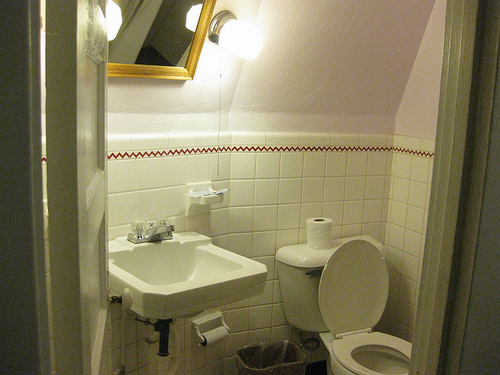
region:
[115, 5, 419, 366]
this room is a small bathroom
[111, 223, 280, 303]
this is the sink for the bathroom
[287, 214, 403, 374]
this is the toilet for the bathroom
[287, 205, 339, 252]
a roll of toilet paper sits on the tank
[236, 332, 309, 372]
there is a garbage can next to the toilet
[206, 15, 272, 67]
this is the light for the bathroom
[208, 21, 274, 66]
the light in the bathroom is on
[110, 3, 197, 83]
this is a mirror hanging on the wall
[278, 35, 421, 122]
the portion of the wall is painted white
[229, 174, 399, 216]
this portion of the wall is made up of white tile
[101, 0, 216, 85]
The mirror on the wall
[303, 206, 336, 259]
The toilet paper on the toilet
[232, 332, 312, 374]
The small trash can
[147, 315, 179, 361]
The black pipe under the sink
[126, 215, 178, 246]
The silver faucet of the sink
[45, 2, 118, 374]
The door of the bathroom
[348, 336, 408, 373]
The opening of the toilet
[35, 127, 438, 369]
The tile on the wall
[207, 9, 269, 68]
The light to the right of the mirror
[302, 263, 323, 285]
The handle of the toilet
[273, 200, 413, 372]
The toilet is white in color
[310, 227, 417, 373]
Toilet seat is up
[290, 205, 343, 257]
Toilet paper is on top of the toilet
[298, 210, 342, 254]
Toilet roll is full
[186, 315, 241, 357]
Toilet roll under the sink is almost empty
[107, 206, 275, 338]
A white colored bathroom sink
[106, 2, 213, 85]
A bathroom mirror on the wall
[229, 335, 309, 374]
A waste basket near the toilet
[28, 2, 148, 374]
Bathroom door is open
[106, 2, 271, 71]
Lights are near the mirror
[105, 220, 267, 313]
White sink in a bathroom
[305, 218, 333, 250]
Toilet tissue on top of a toilet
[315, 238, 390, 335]
Tolite seat lid is up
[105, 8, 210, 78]
Mirror with a gold frame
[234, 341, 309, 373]
Garbage bin with a platic bag in it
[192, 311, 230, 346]
Toilet tissue roll hanging on the wall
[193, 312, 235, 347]
Toilet tissue almost empty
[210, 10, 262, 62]
Bathroom light near the mirror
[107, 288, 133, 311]
White bathroom doorknob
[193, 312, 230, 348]
A white ceramic toilet paper holder.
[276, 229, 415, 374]
A white toilet.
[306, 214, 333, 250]
A roll of white toilet paper.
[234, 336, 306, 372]
A small trash bin.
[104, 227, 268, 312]
A white bathroom sink.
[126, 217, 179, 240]
Silver and clear bathroom sink fixtures.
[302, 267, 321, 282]
A silver toilet flusher.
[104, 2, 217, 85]
A gold framed bathroom mirror.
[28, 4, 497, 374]
A bathroom.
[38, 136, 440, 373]
White tiled wall with a design across the top.